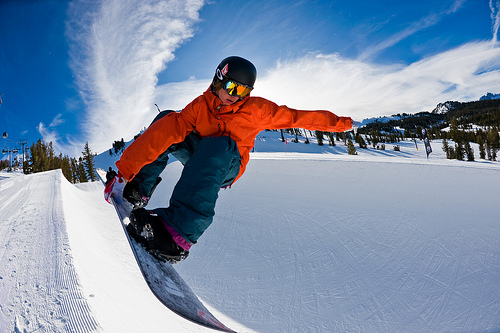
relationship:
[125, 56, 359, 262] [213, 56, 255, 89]
he wearing a helmet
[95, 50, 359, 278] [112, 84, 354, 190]
he wearing a jacket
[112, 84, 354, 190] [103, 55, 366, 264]
jacket worn by snowboarder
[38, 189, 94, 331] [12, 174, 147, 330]
lines in snow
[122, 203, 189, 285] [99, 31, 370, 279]
boots on snowboarder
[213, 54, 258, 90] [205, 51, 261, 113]
helmet on head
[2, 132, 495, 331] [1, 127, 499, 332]
snow covering slope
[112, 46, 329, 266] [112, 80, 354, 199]
man wearing jacket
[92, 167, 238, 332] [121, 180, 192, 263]
board attached to feet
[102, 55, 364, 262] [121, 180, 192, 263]
man has feet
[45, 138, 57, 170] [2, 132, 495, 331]
tree in snow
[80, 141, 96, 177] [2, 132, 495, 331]
tree in snow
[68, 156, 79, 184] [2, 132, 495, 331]
tree in snow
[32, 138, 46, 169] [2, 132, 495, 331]
tree in snow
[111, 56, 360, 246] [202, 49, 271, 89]
boy wearing helmet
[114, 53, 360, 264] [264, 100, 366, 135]
boy has arm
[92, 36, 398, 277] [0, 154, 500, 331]
man on half pipe